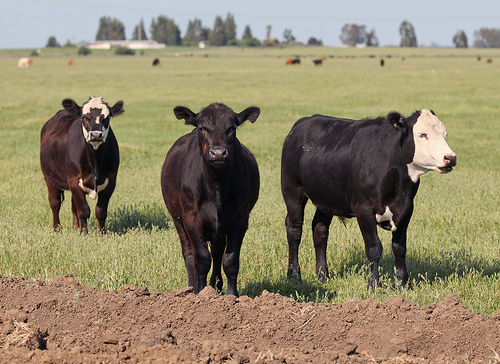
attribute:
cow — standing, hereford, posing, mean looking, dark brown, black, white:
[38, 98, 127, 236]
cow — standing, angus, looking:
[159, 101, 262, 298]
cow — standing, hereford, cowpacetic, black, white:
[280, 107, 457, 293]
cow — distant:
[150, 56, 162, 67]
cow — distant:
[285, 55, 303, 67]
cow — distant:
[17, 57, 32, 67]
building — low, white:
[80, 38, 166, 51]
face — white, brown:
[83, 100, 111, 148]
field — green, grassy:
[0, 61, 499, 319]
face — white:
[416, 110, 455, 172]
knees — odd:
[75, 202, 110, 223]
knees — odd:
[194, 250, 241, 273]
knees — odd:
[364, 239, 408, 262]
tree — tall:
[397, 19, 417, 49]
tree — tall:
[340, 23, 367, 47]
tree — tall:
[223, 11, 236, 45]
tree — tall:
[208, 15, 229, 47]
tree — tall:
[450, 29, 470, 50]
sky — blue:
[0, 0, 497, 47]